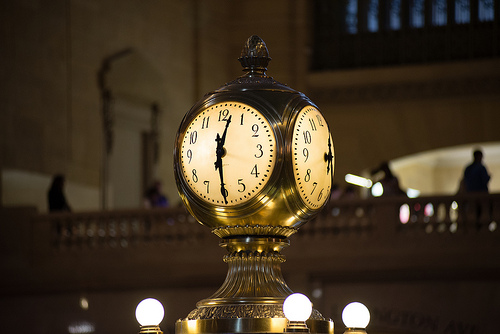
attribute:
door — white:
[104, 119, 154, 236]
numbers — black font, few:
[187, 109, 264, 195]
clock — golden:
[182, 101, 277, 208]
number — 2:
[250, 120, 260, 138]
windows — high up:
[336, 5, 497, 33]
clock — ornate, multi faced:
[162, 97, 264, 228]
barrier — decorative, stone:
[40, 190, 497, 277]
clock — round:
[129, 55, 364, 240]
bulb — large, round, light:
[348, 142, 415, 239]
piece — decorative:
[152, 27, 360, 243]